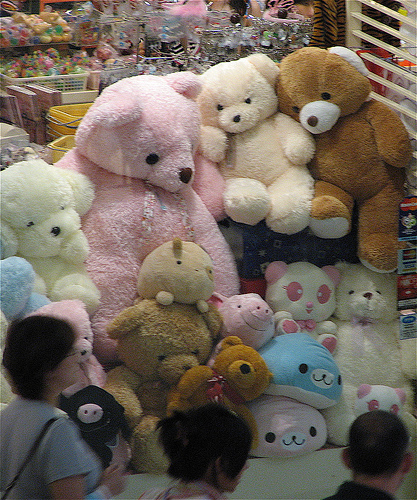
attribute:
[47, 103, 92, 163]
baskets — in back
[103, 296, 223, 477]
teddy bear — small , brown 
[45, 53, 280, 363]
bear — pink , giant 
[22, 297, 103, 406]
teddy bear — pink , small 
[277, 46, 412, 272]
bear — brown, white , big 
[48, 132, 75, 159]
basket — yellow, plastic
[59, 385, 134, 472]
pig doll — black 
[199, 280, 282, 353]
doll — pink 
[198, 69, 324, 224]
toys — bunched together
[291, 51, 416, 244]
toys — bunched together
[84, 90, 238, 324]
toys — bunched together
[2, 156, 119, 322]
toys — bunched together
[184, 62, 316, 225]
bear — big, white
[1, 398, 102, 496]
shirt — blue 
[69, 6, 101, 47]
item — for sale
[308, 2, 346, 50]
item — for sale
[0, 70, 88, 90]
item — for sale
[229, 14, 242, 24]
item — for sale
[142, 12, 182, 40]
item — for sale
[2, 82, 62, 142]
books — in back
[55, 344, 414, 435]
three people — walking by